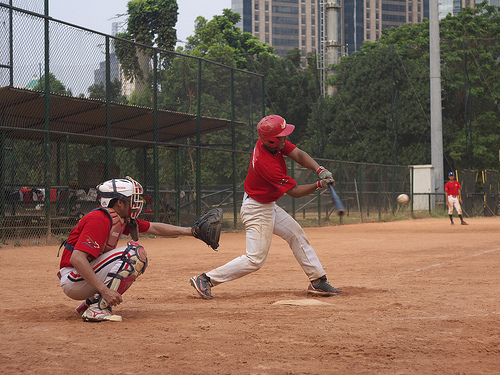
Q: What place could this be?
A: It is a field.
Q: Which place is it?
A: It is a field.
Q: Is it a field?
A: Yes, it is a field.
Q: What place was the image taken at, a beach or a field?
A: It was taken at a field.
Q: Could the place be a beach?
A: No, it is a field.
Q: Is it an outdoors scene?
A: Yes, it is outdoors.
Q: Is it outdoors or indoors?
A: It is outdoors.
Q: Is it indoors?
A: No, it is outdoors.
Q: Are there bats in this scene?
A: Yes, there is a bat.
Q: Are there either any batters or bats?
A: Yes, there is a bat.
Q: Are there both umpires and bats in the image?
A: No, there is a bat but no umpires.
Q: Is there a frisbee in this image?
A: No, there are no frisbees.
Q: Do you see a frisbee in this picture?
A: No, there are no frisbees.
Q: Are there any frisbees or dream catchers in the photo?
A: No, there are no frisbees or dream catchers.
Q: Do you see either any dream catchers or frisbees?
A: No, there are no frisbees or dream catchers.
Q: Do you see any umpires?
A: No, there are no umpires.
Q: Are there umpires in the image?
A: No, there are no umpires.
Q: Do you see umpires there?
A: No, there are no umpires.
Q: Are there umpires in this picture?
A: No, there are no umpires.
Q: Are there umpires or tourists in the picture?
A: No, there are no umpires or tourists.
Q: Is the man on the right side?
A: Yes, the man is on the right of the image.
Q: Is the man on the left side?
A: No, the man is on the right of the image.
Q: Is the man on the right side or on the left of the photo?
A: The man is on the right of the image.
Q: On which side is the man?
A: The man is on the right of the image.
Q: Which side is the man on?
A: The man is on the right of the image.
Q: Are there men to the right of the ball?
A: Yes, there is a man to the right of the ball.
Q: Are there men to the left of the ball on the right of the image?
A: No, the man is to the right of the ball.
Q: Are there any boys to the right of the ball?
A: No, there is a man to the right of the ball.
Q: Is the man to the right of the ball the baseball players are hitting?
A: Yes, the man is to the right of the ball.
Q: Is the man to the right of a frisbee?
A: No, the man is to the right of the ball.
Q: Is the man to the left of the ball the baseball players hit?
A: No, the man is to the right of the ball.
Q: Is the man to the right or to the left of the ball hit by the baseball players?
A: The man is to the right of the ball.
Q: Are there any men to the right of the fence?
A: Yes, there is a man to the right of the fence.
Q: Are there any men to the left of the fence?
A: No, the man is to the right of the fence.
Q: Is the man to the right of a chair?
A: No, the man is to the right of the fence.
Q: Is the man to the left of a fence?
A: No, the man is to the right of a fence.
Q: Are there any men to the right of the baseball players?
A: Yes, there is a man to the right of the baseball players.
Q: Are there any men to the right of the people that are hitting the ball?
A: Yes, there is a man to the right of the baseball players.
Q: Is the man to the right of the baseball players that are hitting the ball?
A: Yes, the man is to the right of the baseball players.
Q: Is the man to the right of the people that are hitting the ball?
A: Yes, the man is to the right of the baseball players.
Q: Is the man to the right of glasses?
A: No, the man is to the right of the baseball players.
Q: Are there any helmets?
A: Yes, there is a helmet.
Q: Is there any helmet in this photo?
A: Yes, there is a helmet.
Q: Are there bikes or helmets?
A: Yes, there is a helmet.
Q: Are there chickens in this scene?
A: No, there are no chickens.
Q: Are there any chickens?
A: No, there are no chickens.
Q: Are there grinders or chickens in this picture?
A: No, there are no chickens or grinders.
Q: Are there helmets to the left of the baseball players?
A: Yes, there is a helmet to the left of the baseball players.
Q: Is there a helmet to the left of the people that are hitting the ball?
A: Yes, there is a helmet to the left of the baseball players.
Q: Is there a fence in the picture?
A: Yes, there is a fence.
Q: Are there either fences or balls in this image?
A: Yes, there is a fence.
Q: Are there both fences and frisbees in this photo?
A: No, there is a fence but no frisbees.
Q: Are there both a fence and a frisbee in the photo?
A: No, there is a fence but no frisbees.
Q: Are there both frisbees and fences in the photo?
A: No, there is a fence but no frisbees.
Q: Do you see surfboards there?
A: No, there are no surfboards.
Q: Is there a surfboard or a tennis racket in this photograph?
A: No, there are no surfboards or rackets.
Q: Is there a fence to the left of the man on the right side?
A: Yes, there is a fence to the left of the man.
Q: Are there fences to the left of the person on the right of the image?
A: Yes, there is a fence to the left of the man.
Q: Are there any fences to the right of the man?
A: No, the fence is to the left of the man.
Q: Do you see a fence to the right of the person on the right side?
A: No, the fence is to the left of the man.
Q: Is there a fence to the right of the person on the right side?
A: No, the fence is to the left of the man.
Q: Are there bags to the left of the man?
A: No, there is a fence to the left of the man.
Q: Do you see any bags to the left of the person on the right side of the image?
A: No, there is a fence to the left of the man.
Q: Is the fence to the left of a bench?
A: No, the fence is to the left of the man.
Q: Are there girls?
A: No, there are no girls.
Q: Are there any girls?
A: No, there are no girls.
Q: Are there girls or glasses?
A: No, there are no girls or glasses.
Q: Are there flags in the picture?
A: No, there are no flags.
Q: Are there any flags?
A: No, there are no flags.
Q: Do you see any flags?
A: No, there are no flags.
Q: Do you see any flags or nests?
A: No, there are no flags or nests.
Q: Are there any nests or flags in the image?
A: No, there are no flags or nests.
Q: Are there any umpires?
A: No, there are no umpires.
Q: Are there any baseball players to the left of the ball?
A: Yes, there are baseball players to the left of the ball.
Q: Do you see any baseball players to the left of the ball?
A: Yes, there are baseball players to the left of the ball.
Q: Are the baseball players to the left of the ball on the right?
A: Yes, the baseball players are to the left of the ball.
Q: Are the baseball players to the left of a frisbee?
A: No, the baseball players are to the left of the ball.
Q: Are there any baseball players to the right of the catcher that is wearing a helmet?
A: Yes, there are baseball players to the right of the catcher.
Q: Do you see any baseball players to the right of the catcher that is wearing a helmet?
A: Yes, there are baseball players to the right of the catcher.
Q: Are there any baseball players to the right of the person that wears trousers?
A: Yes, there are baseball players to the right of the catcher.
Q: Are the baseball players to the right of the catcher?
A: Yes, the baseball players are to the right of the catcher.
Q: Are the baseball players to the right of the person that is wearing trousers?
A: Yes, the baseball players are to the right of the catcher.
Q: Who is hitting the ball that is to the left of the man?
A: The baseball players are hitting the ball.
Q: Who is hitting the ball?
A: The baseball players are hitting the ball.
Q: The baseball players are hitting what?
A: The baseball players are hitting the ball.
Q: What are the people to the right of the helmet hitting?
A: The baseball players are hitting the ball.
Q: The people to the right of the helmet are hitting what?
A: The baseball players are hitting the ball.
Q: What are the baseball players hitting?
A: The baseball players are hitting the ball.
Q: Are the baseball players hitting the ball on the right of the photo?
A: Yes, the baseball players are hitting the ball.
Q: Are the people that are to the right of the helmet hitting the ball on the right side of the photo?
A: Yes, the baseball players are hitting the ball.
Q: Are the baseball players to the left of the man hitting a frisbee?
A: No, the baseball players are hitting the ball.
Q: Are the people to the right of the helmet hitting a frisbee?
A: No, the baseball players are hitting the ball.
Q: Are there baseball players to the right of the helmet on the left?
A: Yes, there are baseball players to the right of the helmet.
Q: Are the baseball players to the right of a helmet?
A: Yes, the baseball players are to the right of a helmet.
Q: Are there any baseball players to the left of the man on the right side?
A: Yes, there are baseball players to the left of the man.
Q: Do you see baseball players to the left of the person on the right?
A: Yes, there are baseball players to the left of the man.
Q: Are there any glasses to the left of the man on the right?
A: No, there are baseball players to the left of the man.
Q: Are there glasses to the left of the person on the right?
A: No, there are baseball players to the left of the man.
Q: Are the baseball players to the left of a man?
A: Yes, the baseball players are to the left of a man.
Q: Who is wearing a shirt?
A: The baseball players are wearing a shirt.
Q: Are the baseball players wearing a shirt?
A: Yes, the baseball players are wearing a shirt.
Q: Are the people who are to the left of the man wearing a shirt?
A: Yes, the baseball players are wearing a shirt.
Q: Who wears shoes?
A: The baseball players wear shoes.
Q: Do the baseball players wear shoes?
A: Yes, the baseball players wear shoes.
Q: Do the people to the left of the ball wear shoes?
A: Yes, the baseball players wear shoes.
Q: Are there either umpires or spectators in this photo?
A: No, there are no umpires or spectators.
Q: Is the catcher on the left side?
A: Yes, the catcher is on the left of the image.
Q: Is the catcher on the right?
A: No, the catcher is on the left of the image.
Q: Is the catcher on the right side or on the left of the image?
A: The catcher is on the left of the image.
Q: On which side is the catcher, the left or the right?
A: The catcher is on the left of the image.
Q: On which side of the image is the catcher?
A: The catcher is on the left of the image.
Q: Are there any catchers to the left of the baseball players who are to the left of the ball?
A: Yes, there is a catcher to the left of the baseball players.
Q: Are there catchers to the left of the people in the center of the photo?
A: Yes, there is a catcher to the left of the baseball players.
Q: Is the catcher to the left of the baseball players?
A: Yes, the catcher is to the left of the baseball players.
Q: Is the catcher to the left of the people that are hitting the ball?
A: Yes, the catcher is to the left of the baseball players.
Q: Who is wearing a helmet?
A: The catcher is wearing a helmet.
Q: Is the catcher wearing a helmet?
A: Yes, the catcher is wearing a helmet.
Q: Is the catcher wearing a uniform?
A: No, the catcher is wearing a helmet.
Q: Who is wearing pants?
A: The catcher is wearing pants.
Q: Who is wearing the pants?
A: The catcher is wearing pants.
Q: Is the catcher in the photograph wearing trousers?
A: Yes, the catcher is wearing trousers.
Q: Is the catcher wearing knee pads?
A: No, the catcher is wearing trousers.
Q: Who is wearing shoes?
A: The catcher is wearing shoes.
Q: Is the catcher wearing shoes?
A: Yes, the catcher is wearing shoes.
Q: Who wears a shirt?
A: The catcher wears a shirt.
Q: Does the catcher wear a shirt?
A: Yes, the catcher wears a shirt.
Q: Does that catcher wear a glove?
A: No, the catcher wears a shirt.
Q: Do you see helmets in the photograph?
A: Yes, there is a helmet.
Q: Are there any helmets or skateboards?
A: Yes, there is a helmet.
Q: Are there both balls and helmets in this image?
A: Yes, there are both a helmet and a ball.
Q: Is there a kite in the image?
A: No, there are no kites.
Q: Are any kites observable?
A: No, there are no kites.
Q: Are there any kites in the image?
A: No, there are no kites.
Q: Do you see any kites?
A: No, there are no kites.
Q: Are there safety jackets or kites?
A: No, there are no kites or safety jackets.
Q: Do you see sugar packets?
A: No, there are no sugar packets.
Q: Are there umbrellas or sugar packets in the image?
A: No, there are no sugar packets or umbrellas.